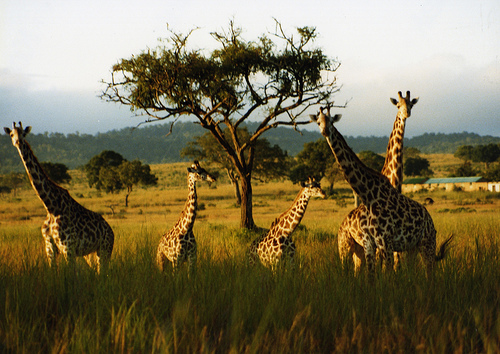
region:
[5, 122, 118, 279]
The giraffe furthest to the left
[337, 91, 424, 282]
The giraffe mostly blocked by another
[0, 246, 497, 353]
Tall grass in front of the animals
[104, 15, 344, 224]
Tall tree behind the giraffes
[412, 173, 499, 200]
The building in the background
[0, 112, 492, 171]
The hills in the background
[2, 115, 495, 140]
The horizon line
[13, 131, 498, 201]
The trees behind the building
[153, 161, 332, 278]
The giraffes looking to the right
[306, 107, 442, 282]
The giraffe standing directly in front of the other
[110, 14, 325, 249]
tree with green leaves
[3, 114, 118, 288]
large adult giraffe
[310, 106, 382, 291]
large adult giraffe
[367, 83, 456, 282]
large adult giraffe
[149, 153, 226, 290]
small young giraffe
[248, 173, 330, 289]
small young giraffe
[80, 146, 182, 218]
tree with green leaves at a distance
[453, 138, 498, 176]
tree with green leaves at a distance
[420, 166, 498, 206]
whsite brick building with green roof at a distance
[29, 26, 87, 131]
hazy blue skies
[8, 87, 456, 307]
Five giraffes standing field.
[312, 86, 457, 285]
Two seem largest group.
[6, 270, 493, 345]
Textured high grass field.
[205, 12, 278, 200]
Lone scraggly tree centered.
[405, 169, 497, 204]
Buildings Zoo compound seen.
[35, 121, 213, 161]
Vegetation many types background.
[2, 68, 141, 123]
Sky horizon hazy smoggy.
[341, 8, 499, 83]
Dim partially cloudy sky.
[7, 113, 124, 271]
Giraffe looks toward camera.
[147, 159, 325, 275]
Adolescent giraffes learn parents.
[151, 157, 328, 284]
two baby giraffes standing in a grassy field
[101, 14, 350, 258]
tree in the middle of the grassy field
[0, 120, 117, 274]
one adult giraffe looking at the camera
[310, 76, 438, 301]
two adult giraffes looking at the camera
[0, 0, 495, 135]
sky is slightly cloudy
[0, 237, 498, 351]
tall grass in the field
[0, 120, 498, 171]
row of tall trees in the background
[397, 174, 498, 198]
row of houses in background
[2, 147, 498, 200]
row of small trees in the background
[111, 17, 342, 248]
tall tree behind the baby giraffe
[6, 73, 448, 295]
giraffes standing in field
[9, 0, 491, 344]
this is an outdoor daytime scene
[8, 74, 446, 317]
five giraffes in grass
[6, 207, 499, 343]
tall green grass in foreground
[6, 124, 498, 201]
green trees in distance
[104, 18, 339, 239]
green tree in foreground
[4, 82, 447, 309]
brown and white giraffes standing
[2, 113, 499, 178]
green hills in background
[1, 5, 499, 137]
blue sunny cloudy sky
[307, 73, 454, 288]
two giraffes standing with necks crossed